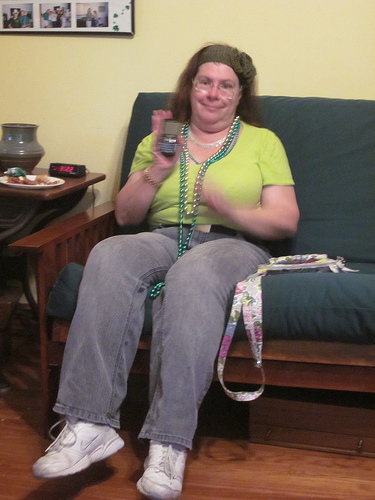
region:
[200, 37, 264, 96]
Headband around woman's head.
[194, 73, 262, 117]
Glasses on woman's face.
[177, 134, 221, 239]
Necklaces around woman's neck.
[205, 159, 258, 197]
Woman wearing green shirt.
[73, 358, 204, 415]
Woman wearing gray pants.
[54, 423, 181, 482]
Woman wearing white tennis shoes.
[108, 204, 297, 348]
Woman sitting on futon.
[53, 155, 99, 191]
Digital clock on table near woman.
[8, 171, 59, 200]
White plate sitting on table.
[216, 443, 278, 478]
Brown hardwood floors in room.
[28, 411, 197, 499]
a pair of white sneakers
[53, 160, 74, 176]
red numbers on the alarm clock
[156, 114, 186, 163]
a cell phone in the woman's hand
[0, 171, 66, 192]
a plate of food on the table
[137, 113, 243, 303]
a long green beaded necklace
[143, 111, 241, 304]
several beaded necklaces around the woman's neck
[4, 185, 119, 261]
the wooden arm of the couch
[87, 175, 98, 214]
part of the cord to the alarm clock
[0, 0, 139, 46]
part of a picture on the wall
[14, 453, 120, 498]
a shadow on the floor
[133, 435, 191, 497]
a woman's white tennis shoe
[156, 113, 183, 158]
a small black cellphone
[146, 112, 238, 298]
a long green bead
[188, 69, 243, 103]
a woman's eyeglasses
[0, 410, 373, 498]
part of a brown wooden floor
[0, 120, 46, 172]
a small gray vase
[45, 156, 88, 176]
a small black clock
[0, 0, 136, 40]
part of a black and white picture frame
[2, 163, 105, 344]
part of a brown table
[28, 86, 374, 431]
part of a futon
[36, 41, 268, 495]
A lady sitting on a couch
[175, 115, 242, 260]
Several beaded necklaces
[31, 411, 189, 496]
White Nike shoes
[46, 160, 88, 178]
A black alarm clock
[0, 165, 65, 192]
A white plate of food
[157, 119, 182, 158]
A cell phone being shown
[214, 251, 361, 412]
A floral decorated hand bag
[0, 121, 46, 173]
A grey vase on the desk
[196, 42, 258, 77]
A gray hair scrunchie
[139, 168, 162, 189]
A gold bracelet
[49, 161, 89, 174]
digital clock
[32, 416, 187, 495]
white shoes with a Nike symbol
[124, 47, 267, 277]
woman holding up a mobile phone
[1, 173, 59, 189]
white plate of food on the end table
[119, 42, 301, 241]
woman wearing a green headband and beaded necklaces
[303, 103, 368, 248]
blue futon mattress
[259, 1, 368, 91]
pale yellow wall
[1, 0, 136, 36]
framed photos hanging on the wall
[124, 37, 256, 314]
woman wearing glasses and jeans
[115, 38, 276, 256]
woman wearing a bracelet and beaded necklaces